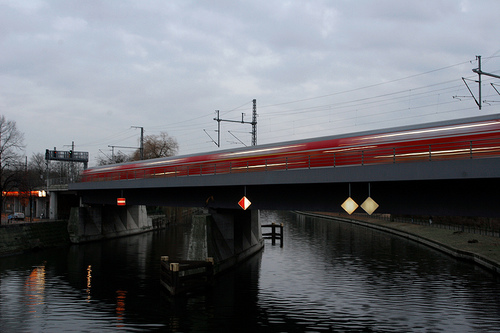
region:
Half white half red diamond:
[235, 194, 252, 211]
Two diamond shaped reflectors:
[339, 194, 379, 216]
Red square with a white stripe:
[115, 195, 125, 207]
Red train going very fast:
[79, 114, 499, 184]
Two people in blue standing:
[5, 211, 14, 224]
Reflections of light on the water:
[19, 261, 126, 331]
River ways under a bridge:
[69, 200, 499, 295]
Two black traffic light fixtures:
[51, 148, 75, 160]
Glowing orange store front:
[0, 188, 45, 198]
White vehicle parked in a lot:
[11, 210, 25, 220]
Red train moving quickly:
[41, 116, 498, 188]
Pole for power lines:
[205, 80, 261, 145]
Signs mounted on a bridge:
[104, 185, 391, 215]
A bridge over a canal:
[27, 156, 497, 298]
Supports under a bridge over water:
[65, 195, 275, 270]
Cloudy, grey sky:
[25, 15, 226, 90]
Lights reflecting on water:
[16, 252, 133, 326]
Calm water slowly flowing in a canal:
[290, 212, 356, 327]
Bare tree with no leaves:
[0, 115, 26, 170]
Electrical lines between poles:
[265, 82, 447, 124]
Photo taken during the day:
[8, 5, 492, 323]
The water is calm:
[2, 213, 487, 325]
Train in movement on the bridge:
[72, 110, 496, 179]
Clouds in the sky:
[0, 24, 472, 129]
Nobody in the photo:
[10, 7, 488, 327]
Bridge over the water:
[89, 162, 439, 288]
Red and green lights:
[32, 140, 89, 167]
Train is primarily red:
[34, 143, 491, 180]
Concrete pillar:
[151, 195, 266, 293]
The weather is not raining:
[6, 13, 484, 323]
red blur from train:
[344, 125, 397, 183]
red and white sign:
[221, 185, 268, 227]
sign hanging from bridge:
[240, 192, 278, 244]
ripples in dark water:
[307, 313, 332, 326]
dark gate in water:
[263, 223, 293, 255]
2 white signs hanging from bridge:
[331, 184, 411, 242]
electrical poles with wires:
[211, 103, 278, 157]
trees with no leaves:
[11, 119, 36, 174]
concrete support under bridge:
[174, 213, 246, 257]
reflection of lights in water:
[23, 271, 85, 327]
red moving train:
[75, 115, 499, 184]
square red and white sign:
[237, 195, 251, 208]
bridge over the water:
[3, 159, 498, 253]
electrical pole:
[465, 55, 497, 114]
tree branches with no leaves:
[0, 119, 22, 178]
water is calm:
[1, 215, 496, 327]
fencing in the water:
[261, 221, 286, 245]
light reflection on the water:
[24, 265, 128, 307]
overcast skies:
[3, 3, 490, 160]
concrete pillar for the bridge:
[182, 205, 259, 274]